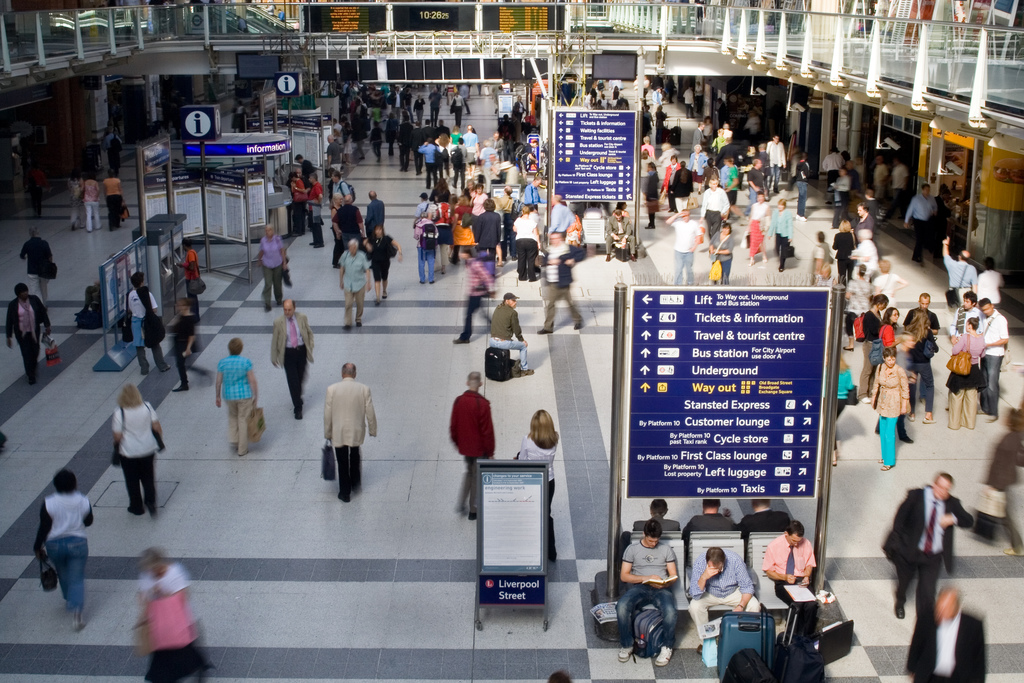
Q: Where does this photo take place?
A: In a airport.